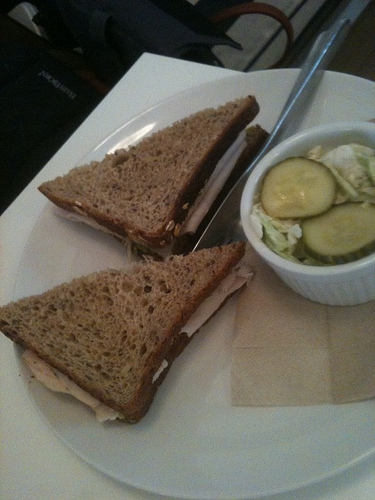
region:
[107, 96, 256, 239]
brown bread on plate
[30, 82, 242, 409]
bread halved on bias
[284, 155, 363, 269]
green pickles in ramekin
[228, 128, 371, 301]
white ramekin on plate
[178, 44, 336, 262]
steel knife on plate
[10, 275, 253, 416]
white meat in sandwich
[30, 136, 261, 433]
two halves of sandwich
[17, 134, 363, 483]
white and round plate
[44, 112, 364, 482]
plate on white mat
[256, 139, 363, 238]
coleslaw in white ramekin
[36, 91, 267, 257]
a cut in half sandwich.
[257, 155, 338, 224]
a pickle slice in a white bowl.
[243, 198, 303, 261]
lettuce inside of a white bowl.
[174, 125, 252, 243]
meat in a sandwich half.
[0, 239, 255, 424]
a half of a sandwich.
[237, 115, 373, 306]
a white bowl filled with sandwich toppings.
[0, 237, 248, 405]
a cut in half slice of bread.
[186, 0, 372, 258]
a knife sitting on a plate.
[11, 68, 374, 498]
a large white plate.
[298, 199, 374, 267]
a green pickle slice.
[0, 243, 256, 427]
triangle of a turkey sandwich on wheat bread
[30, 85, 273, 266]
triangle of a turkey sandwich on wheat bread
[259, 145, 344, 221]
crisp pale green pickle chip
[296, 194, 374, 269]
crisp pale green pickle chip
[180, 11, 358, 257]
shiny silver butter knife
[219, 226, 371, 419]
light brown paper napkin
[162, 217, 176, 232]
light brown oat stuck to bread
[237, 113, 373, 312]
shiny white ceramic ramikin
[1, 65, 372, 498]
shiny white ceramic plate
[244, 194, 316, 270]
light green leafy vegetable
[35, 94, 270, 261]
half of a cut sandwich at top of plate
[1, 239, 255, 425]
bottom half of a cut sandwich on plate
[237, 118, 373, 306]
white bowl full of chopped lettuce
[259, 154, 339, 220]
top sliced green cucumber in bowl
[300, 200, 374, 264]
bottom sliced green cucumber in bowl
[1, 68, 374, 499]
round white porcelain dinner plate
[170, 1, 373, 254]
silver metal butter knife on plate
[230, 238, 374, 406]
light brown paper napkin under bowl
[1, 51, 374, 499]
white placemat under white dinner plate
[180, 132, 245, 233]
sliced turkey hanging from sandwich onto knife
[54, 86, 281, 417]
a sandwich on a plate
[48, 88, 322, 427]
a sandwich on a white plate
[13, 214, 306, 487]
a plate with a sandwich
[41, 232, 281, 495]
a sandwich cut in half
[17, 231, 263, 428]
a wheat bread sandwich cut in half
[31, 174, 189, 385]
a wheat bread sandiwhc on a white plate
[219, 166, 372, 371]
a cup on a plate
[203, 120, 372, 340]
a cup on a white plate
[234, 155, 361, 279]
pickles in a bowl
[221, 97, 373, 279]
pickles in a white bowl